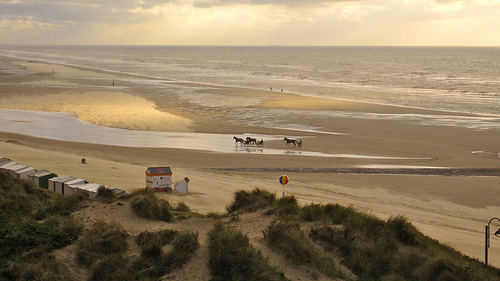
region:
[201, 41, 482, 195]
the beach is wet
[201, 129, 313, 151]
there are horses on the beach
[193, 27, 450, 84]
the water is calm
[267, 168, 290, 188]
a colored ball in the dirt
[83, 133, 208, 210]
the sand is beige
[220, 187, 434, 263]
the grass is tall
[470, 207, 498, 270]
the lamp is off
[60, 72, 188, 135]
the sun is shining on the sand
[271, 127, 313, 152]
the horse is pulling a man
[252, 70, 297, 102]
people walking on the beach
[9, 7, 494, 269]
Golden beach scene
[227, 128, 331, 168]
Horses on a beach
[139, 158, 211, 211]
Shack on the sand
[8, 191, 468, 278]
Sand dunes on cliff over beach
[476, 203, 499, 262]
Metal light pole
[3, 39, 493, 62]
Horizon where the water meets the sky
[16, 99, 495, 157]
Wet sand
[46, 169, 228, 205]
Dry sand above the waterline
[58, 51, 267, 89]
Small waves breaking on the beach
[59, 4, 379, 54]
Golden rays of sun shining thru the clouds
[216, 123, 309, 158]
several horses on wet sand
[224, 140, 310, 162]
reflection of horses on wet sand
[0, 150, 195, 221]
small building on side of ocean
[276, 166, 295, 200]
a red, yellow and blue ball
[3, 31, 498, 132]
water of sea is choppy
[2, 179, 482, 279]
plants growing on the sand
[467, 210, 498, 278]
a pole on the shore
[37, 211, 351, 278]
bold spaces on field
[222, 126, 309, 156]
horses walking to the left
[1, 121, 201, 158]
part of wet sand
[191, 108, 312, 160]
horse and buggies on beach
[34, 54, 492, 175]
tide is out on the beach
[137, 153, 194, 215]
small building on beach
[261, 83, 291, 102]
people walking at the water's edge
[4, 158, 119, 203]
row of buildings on beach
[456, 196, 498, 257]
lamp post on beach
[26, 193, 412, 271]
grassy dune beside the beach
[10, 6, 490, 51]
cloudy sky over the beach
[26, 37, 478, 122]
calm waters at the beach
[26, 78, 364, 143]
patches of sunshine on the beach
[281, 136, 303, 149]
horse walking on beach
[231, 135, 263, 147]
horses walking along shore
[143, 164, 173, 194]
white house on beach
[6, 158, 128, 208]
changing room stalls on beach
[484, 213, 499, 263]
black metal light on pole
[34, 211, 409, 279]
shrubs in beach dune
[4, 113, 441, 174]
water pool from ocean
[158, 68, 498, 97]
white foam from ocean wave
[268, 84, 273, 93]
person swimming in ocean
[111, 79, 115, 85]
person walking on beach